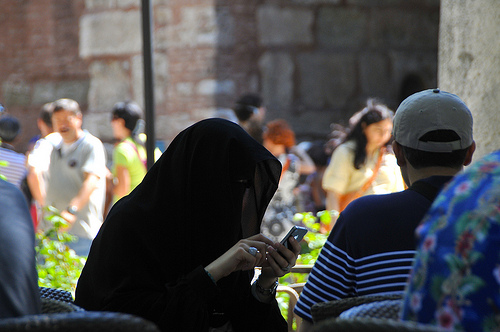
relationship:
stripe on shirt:
[348, 249, 422, 261] [287, 173, 450, 309]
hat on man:
[390, 87, 484, 151] [284, 76, 482, 327]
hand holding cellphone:
[277, 223, 307, 256] [282, 222, 310, 244]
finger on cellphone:
[284, 229, 308, 256] [282, 222, 310, 244]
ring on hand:
[247, 243, 257, 259] [233, 234, 282, 281]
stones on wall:
[305, 52, 360, 106] [7, 2, 433, 144]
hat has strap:
[390, 87, 484, 151] [412, 126, 461, 156]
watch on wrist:
[253, 277, 280, 295] [251, 268, 288, 312]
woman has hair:
[327, 99, 407, 214] [335, 103, 393, 169]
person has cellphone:
[81, 113, 301, 325] [282, 222, 310, 244]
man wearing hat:
[284, 76, 482, 327] [390, 87, 484, 151]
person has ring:
[81, 113, 301, 325] [247, 243, 257, 259]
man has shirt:
[110, 136, 168, 206] [117, 135, 154, 202]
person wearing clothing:
[81, 113, 301, 325] [74, 116, 292, 330]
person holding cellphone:
[81, 113, 301, 325] [282, 222, 310, 244]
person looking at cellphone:
[81, 113, 301, 325] [282, 222, 310, 244]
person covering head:
[81, 113, 301, 325] [129, 103, 287, 236]